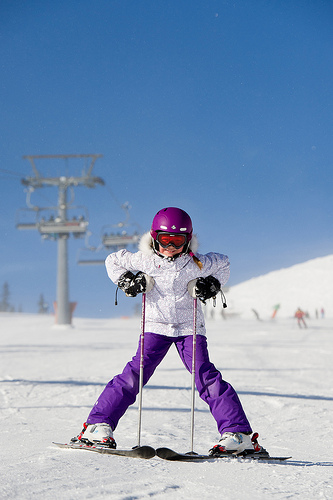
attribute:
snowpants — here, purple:
[114, 353, 261, 424]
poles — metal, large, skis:
[188, 308, 259, 355]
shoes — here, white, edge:
[91, 423, 93, 424]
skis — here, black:
[103, 438, 167, 462]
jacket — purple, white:
[140, 293, 196, 317]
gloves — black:
[200, 280, 215, 294]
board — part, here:
[150, 448, 169, 462]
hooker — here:
[264, 298, 265, 299]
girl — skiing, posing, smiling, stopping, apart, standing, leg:
[95, 210, 244, 416]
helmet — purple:
[139, 199, 191, 228]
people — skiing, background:
[221, 293, 317, 322]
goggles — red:
[136, 229, 189, 247]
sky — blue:
[159, 24, 188, 40]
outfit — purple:
[103, 256, 269, 435]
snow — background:
[0, 347, 79, 386]